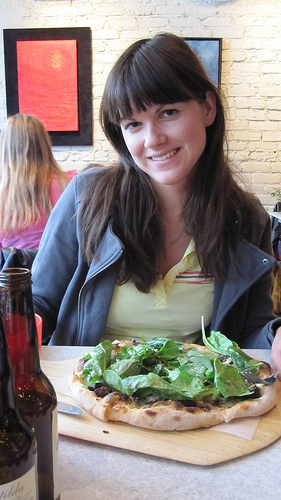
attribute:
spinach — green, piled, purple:
[81, 315, 277, 404]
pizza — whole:
[68, 336, 277, 431]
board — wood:
[40, 345, 279, 467]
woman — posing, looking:
[27, 27, 279, 372]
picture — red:
[1, 25, 96, 152]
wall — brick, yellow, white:
[1, 0, 279, 220]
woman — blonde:
[3, 110, 79, 256]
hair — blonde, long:
[1, 111, 67, 229]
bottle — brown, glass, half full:
[2, 265, 60, 499]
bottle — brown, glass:
[0, 318, 38, 499]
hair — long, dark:
[74, 33, 250, 296]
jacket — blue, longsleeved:
[29, 166, 280, 352]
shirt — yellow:
[98, 230, 215, 346]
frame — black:
[1, 26, 97, 148]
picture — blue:
[182, 36, 222, 94]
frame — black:
[176, 36, 222, 93]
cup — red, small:
[1, 311, 41, 385]